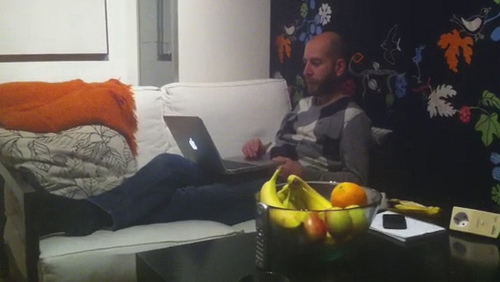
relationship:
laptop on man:
[161, 112, 285, 177] [23, 34, 389, 237]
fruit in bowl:
[268, 167, 366, 210] [259, 182, 380, 254]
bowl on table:
[259, 182, 380, 254] [132, 187, 500, 280]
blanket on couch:
[0, 73, 144, 140] [2, 74, 306, 279]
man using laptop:
[23, 34, 389, 237] [161, 112, 285, 177]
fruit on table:
[268, 167, 366, 210] [132, 187, 500, 280]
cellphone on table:
[382, 212, 408, 231] [132, 187, 500, 280]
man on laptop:
[23, 34, 389, 237] [161, 112, 285, 177]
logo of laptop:
[186, 135, 201, 154] [161, 112, 285, 177]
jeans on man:
[80, 140, 296, 237] [23, 34, 389, 237]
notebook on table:
[369, 208, 449, 241] [132, 187, 500, 280]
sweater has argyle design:
[251, 93, 373, 193] [287, 117, 342, 168]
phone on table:
[251, 200, 273, 271] [132, 187, 500, 280]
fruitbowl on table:
[259, 182, 380, 254] [132, 187, 500, 280]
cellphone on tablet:
[382, 212, 408, 231] [369, 208, 449, 241]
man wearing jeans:
[23, 34, 389, 237] [80, 140, 296, 237]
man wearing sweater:
[23, 34, 389, 237] [251, 93, 373, 193]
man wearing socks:
[23, 34, 389, 237] [22, 167, 104, 238]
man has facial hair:
[23, 34, 389, 237] [296, 67, 340, 100]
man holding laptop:
[23, 34, 389, 237] [161, 112, 285, 177]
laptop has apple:
[161, 112, 285, 177] [186, 135, 201, 154]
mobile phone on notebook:
[382, 212, 408, 231] [369, 208, 449, 241]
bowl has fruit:
[259, 182, 380, 254] [268, 167, 366, 210]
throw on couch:
[0, 73, 144, 140] [2, 74, 306, 279]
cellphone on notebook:
[382, 212, 408, 231] [369, 208, 449, 241]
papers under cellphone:
[369, 208, 449, 241] [382, 212, 408, 231]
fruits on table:
[259, 182, 380, 254] [132, 187, 500, 280]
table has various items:
[132, 187, 500, 280] [250, 166, 499, 281]